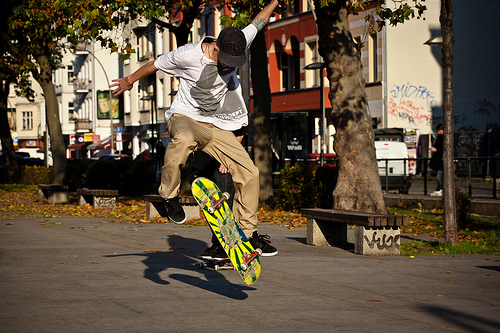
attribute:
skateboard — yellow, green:
[192, 184, 267, 286]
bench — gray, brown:
[76, 178, 128, 217]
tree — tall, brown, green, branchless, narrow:
[311, 13, 403, 221]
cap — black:
[221, 30, 252, 63]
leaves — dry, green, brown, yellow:
[47, 24, 70, 56]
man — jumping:
[141, 32, 269, 193]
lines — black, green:
[220, 200, 225, 231]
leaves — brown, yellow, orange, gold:
[19, 189, 54, 219]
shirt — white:
[165, 51, 256, 114]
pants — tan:
[173, 120, 251, 209]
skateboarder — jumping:
[174, 29, 252, 149]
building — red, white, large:
[282, 10, 498, 149]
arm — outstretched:
[252, 0, 278, 32]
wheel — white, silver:
[239, 261, 253, 278]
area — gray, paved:
[27, 239, 159, 315]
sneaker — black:
[163, 195, 191, 227]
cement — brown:
[110, 262, 302, 314]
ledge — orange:
[274, 24, 329, 43]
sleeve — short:
[159, 49, 188, 74]